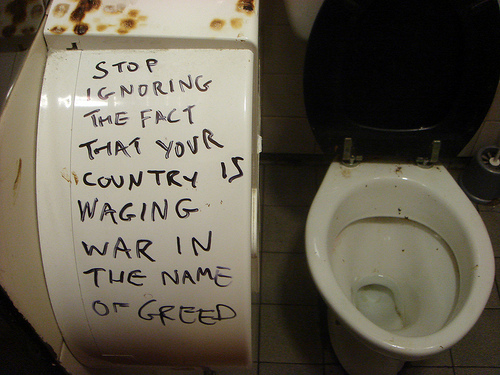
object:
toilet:
[302, 4, 496, 373]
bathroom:
[1, 0, 498, 371]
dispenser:
[40, 3, 253, 368]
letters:
[91, 60, 110, 81]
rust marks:
[72, 22, 89, 36]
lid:
[302, 2, 498, 169]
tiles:
[448, 306, 500, 373]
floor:
[260, 160, 497, 372]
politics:
[76, 58, 243, 330]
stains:
[395, 206, 403, 219]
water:
[349, 275, 424, 332]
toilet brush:
[455, 145, 500, 207]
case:
[460, 146, 498, 206]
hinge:
[340, 137, 440, 166]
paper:
[250, 254, 262, 296]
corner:
[457, 131, 499, 203]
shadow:
[262, 0, 336, 369]